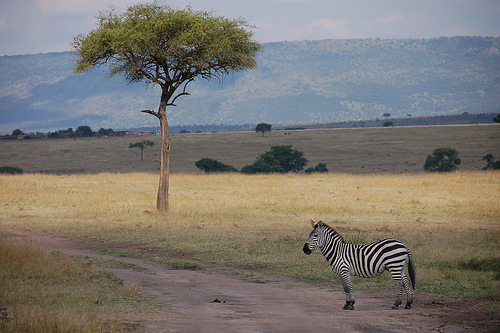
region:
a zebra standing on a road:
[296, 214, 425, 316]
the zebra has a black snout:
[301, 242, 312, 256]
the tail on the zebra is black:
[404, 255, 417, 292]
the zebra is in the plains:
[6, 118, 499, 330]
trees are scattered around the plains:
[2, 107, 497, 207]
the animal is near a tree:
[71, 5, 431, 313]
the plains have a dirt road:
[1, 219, 487, 331]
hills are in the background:
[3, 24, 496, 148]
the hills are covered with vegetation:
[6, 32, 499, 144]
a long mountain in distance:
[18, 29, 398, 129]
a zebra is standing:
[252, 193, 445, 318]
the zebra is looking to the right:
[281, 205, 456, 318]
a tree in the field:
[67, 2, 239, 280]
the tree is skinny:
[85, 20, 230, 247]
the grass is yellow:
[175, 175, 313, 237]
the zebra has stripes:
[303, 208, 445, 308]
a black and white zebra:
[284, 201, 414, 302]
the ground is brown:
[132, 260, 273, 327]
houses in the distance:
[87, 123, 188, 134]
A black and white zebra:
[302, 215, 426, 320]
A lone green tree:
[71, 0, 265, 222]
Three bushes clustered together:
[197, 135, 335, 186]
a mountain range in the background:
[290, 33, 490, 116]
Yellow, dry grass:
[62, 177, 153, 226]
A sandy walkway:
[127, 236, 267, 331]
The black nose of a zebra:
[300, 227, 314, 272]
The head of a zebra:
[299, 214, 340, 266]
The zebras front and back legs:
[336, 270, 413, 312]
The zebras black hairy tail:
[404, 239, 424, 295]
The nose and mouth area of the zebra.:
[300, 240, 316, 260]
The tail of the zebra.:
[400, 245, 420, 281]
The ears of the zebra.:
[307, 215, 322, 230]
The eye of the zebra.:
[310, 226, 316, 233]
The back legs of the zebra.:
[390, 280, 411, 305]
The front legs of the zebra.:
[330, 270, 356, 309]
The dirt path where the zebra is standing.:
[60, 217, 490, 331]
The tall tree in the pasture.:
[69, 12, 259, 241]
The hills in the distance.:
[16, 49, 498, 126]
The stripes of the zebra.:
[304, 220, 425, 298]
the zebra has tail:
[368, 227, 416, 331]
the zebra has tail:
[257, 157, 410, 319]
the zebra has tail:
[320, 189, 412, 311]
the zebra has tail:
[331, 150, 447, 330]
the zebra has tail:
[334, 245, 426, 325]